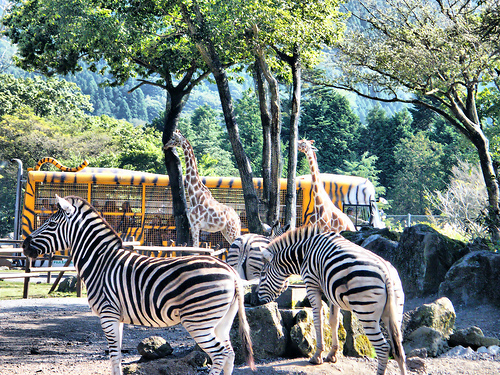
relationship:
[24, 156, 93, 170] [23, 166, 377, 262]
snake on top of bus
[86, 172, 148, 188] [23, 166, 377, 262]
stripes on side of bus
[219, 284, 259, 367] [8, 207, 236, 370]
tail attached to zebra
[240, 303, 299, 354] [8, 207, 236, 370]
rocks behind zebra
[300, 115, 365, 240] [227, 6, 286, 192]
giraffe standing by tree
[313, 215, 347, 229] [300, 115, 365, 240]
spots on top of giraffe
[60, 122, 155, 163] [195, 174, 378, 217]
trees behind bus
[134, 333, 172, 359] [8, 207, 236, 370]
rock underneath zebra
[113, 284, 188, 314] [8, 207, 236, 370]
stripes on top of zebra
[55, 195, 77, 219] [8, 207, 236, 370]
ear attached to zebra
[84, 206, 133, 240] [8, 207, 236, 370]
mane attached to zebra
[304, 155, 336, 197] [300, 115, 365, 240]
neck attached to giraffe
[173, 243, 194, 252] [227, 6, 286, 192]
trunk attached to tree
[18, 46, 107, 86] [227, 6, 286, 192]
leaves attached to tree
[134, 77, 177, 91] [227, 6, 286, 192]
branch attached to tree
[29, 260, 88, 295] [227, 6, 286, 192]
fence near tree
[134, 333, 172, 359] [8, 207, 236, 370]
rock next to zebra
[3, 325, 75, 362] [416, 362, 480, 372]
shadow on top of ground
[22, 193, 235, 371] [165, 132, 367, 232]
zebra near giraffes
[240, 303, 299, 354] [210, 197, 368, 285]
rocks on side of animals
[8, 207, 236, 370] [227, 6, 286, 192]
zebra licking tree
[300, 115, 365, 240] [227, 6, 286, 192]
giraffe next to tree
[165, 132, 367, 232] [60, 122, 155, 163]
giraffes under trees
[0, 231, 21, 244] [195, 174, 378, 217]
pipe on back of bus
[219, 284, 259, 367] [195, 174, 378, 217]
tail on top of bus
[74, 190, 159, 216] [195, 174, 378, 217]
people inside of bus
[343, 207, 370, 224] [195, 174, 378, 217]
driver inside of bus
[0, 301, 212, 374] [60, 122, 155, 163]
shadow of trees